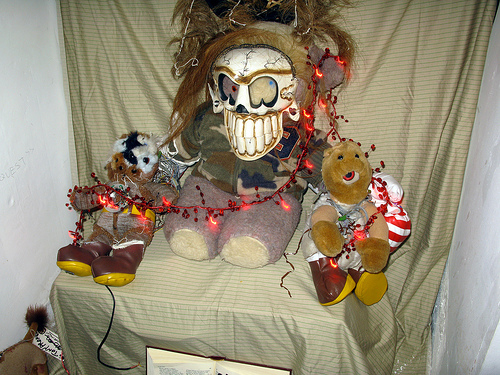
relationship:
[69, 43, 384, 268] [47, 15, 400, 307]
lights are draped around bears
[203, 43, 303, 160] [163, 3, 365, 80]
mask has hair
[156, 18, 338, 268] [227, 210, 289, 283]
teddy bear has leg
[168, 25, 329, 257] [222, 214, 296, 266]
bear has leg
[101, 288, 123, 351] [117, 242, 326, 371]
wiring running down table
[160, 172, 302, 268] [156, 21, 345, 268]
feet of plush teddy bear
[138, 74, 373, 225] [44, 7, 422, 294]
wiring across bears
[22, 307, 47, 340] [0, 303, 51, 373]
tail of plush toy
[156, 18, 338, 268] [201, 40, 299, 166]
teddy bear wears mask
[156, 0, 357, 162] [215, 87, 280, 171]
mask has teeth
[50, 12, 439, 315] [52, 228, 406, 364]
bears sit on table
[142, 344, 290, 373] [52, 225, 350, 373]
book on table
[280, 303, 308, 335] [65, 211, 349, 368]
edge of a board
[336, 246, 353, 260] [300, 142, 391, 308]
edge of a bear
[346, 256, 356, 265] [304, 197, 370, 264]
part of a sweater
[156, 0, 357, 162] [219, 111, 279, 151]
mask with teeth